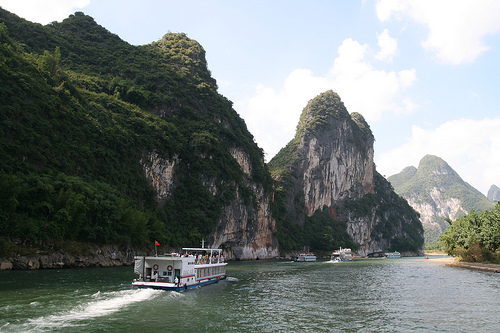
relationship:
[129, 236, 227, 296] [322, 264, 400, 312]
boat on water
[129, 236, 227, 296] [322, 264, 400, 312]
boat in water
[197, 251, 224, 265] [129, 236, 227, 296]
people on boat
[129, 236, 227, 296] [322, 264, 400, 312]
boat above water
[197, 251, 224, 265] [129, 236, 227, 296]
people in boat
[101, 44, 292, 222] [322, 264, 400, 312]
mountain near water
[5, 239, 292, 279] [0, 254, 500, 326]
shoreline of water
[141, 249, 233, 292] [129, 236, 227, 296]
many people on boat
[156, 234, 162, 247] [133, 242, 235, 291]
flag on boat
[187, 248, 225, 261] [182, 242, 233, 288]
people standing on deck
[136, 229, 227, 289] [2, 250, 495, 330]
boat on water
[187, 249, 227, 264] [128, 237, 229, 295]
people are on boat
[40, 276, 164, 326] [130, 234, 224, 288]
water behind boat